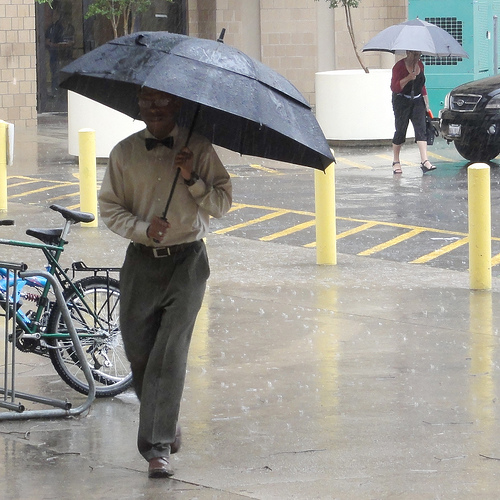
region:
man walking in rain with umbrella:
[84, 45, 336, 477]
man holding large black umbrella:
[60, 21, 345, 282]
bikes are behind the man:
[5, 179, 136, 412]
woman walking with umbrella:
[364, 10, 458, 195]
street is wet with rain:
[243, 219, 455, 422]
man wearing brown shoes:
[110, 422, 210, 478]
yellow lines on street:
[356, 200, 449, 277]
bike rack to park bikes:
[0, 312, 101, 437]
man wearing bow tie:
[129, 125, 195, 171]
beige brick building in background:
[253, 0, 319, 88]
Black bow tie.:
[139, 129, 184, 154]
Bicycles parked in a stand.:
[2, 207, 135, 404]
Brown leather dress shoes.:
[134, 416, 191, 478]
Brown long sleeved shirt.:
[96, 124, 244, 249]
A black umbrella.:
[51, 15, 334, 177]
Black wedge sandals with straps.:
[382, 154, 444, 178]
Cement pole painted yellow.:
[453, 150, 498, 297]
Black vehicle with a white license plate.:
[438, 70, 498, 167]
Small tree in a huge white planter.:
[326, 1, 375, 75]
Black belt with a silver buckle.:
[121, 237, 213, 262]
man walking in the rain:
[57, 8, 325, 470]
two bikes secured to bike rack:
[2, 197, 146, 446]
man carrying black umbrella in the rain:
[69, 22, 346, 258]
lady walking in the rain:
[365, 5, 457, 180]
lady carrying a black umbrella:
[358, 4, 475, 186]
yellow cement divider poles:
[285, 142, 499, 302]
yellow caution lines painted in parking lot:
[234, 192, 499, 305]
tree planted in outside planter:
[310, 1, 427, 158]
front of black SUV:
[436, 73, 495, 165]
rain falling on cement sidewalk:
[245, 226, 498, 481]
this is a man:
[105, 113, 200, 456]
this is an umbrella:
[77, 36, 317, 125]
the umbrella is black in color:
[71, 59, 271, 97]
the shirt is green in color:
[114, 154, 164, 215]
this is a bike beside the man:
[0, 255, 101, 362]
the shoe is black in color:
[413, 162, 443, 174]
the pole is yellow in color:
[464, 164, 492, 290]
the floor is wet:
[207, 294, 434, 439]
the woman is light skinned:
[420, 142, 425, 146]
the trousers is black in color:
[120, 264, 195, 449]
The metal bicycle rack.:
[1, 263, 96, 470]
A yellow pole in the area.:
[463, 161, 493, 292]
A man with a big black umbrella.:
[55, 20, 334, 479]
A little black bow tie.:
[144, 135, 177, 151]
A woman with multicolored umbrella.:
[361, 13, 466, 178]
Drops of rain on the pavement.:
[260, 255, 420, 417]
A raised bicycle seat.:
[49, 200, 93, 240]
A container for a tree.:
[322, 0, 396, 142]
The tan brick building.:
[0, 0, 44, 146]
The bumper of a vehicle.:
[441, 73, 498, 162]